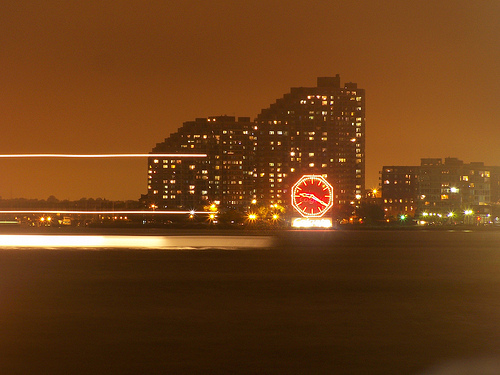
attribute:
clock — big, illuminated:
[285, 166, 342, 221]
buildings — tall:
[150, 92, 395, 167]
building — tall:
[267, 77, 405, 222]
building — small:
[378, 156, 498, 228]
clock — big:
[289, 173, 336, 235]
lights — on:
[292, 214, 331, 224]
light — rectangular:
[285, 216, 332, 229]